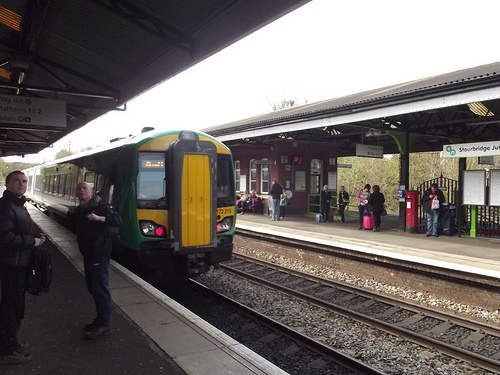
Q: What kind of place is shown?
A: It is a station.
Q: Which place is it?
A: It is a station.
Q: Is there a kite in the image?
A: No, there are no kites.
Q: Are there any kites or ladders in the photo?
A: No, there are no kites or ladders.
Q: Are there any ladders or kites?
A: No, there are no kites or ladders.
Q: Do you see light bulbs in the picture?
A: No, there are no light bulbs.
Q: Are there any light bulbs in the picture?
A: No, there are no light bulbs.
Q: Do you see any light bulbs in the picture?
A: No, there are no light bulbs.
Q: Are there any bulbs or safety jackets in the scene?
A: No, there are no bulbs or safety jackets.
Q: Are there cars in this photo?
A: No, there are no cars.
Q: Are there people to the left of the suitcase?
A: Yes, there are people to the left of the suitcase.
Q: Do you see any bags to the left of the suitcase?
A: No, there are people to the left of the suitcase.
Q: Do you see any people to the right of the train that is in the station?
A: Yes, there are people to the right of the train.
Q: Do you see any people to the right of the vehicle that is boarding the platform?
A: Yes, there are people to the right of the train.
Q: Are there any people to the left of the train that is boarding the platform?
A: No, the people are to the right of the train.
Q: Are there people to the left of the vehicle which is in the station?
A: No, the people are to the right of the train.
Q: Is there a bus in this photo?
A: No, there are no buses.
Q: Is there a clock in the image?
A: No, there are no clocks.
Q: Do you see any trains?
A: Yes, there is a train.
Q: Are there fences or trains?
A: Yes, there is a train.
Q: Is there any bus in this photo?
A: No, there are no buses.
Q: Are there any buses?
A: No, there are no buses.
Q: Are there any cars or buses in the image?
A: No, there are no buses or cars.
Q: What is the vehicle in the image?
A: The vehicle is a train.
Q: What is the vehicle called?
A: The vehicle is a train.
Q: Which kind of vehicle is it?
A: The vehicle is a train.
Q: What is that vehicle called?
A: This is a train.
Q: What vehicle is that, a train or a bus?
A: This is a train.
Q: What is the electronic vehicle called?
A: The vehicle is a train.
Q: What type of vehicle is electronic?
A: The vehicle is a train.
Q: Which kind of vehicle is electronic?
A: The vehicle is a train.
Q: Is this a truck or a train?
A: This is a train.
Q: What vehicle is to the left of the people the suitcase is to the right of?
A: The vehicle is a train.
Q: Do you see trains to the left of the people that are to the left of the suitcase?
A: Yes, there is a train to the left of the people.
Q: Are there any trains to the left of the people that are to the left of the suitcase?
A: Yes, there is a train to the left of the people.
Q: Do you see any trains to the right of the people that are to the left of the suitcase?
A: No, the train is to the left of the people.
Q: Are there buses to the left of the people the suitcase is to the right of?
A: No, there is a train to the left of the people.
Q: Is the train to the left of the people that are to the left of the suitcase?
A: Yes, the train is to the left of the people.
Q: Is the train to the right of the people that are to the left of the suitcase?
A: No, the train is to the left of the people.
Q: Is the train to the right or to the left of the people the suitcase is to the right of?
A: The train is to the left of the people.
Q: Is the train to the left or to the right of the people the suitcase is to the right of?
A: The train is to the left of the people.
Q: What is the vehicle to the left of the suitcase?
A: The vehicle is a train.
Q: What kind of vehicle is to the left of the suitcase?
A: The vehicle is a train.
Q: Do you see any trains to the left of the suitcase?
A: Yes, there is a train to the left of the suitcase.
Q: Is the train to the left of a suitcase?
A: Yes, the train is to the left of a suitcase.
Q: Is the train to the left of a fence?
A: No, the train is to the left of a suitcase.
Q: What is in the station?
A: The train is in the station.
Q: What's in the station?
A: The train is in the station.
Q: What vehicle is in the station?
A: The vehicle is a train.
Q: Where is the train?
A: The train is in the station.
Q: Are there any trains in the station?
A: Yes, there is a train in the station.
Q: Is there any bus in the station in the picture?
A: No, there is a train in the station.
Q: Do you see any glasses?
A: No, there are no glasses.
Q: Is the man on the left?
A: Yes, the man is on the left of the image.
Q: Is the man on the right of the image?
A: No, the man is on the left of the image.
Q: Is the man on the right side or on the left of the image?
A: The man is on the left of the image.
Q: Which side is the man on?
A: The man is on the left of the image.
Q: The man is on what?
A: The man is on the platform.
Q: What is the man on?
A: The man is on the platform.